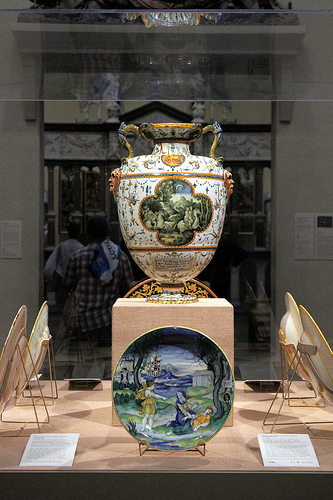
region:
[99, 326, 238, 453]
gold rimmed plate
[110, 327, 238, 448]
gold rimmed plate with a painting drawn in the middle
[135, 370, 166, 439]
painting of an angel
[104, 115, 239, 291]
vase with painting on it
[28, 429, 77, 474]
white piece of paper with text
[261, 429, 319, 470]
white piece of paper with text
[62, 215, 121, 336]
reflection of a person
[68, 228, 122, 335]
reflection of a person in a plaid shirt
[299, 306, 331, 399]
gold rimmed plate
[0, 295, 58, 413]
gold rimmed plates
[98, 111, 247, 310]
two handled ornate vase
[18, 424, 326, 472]
two white placards in front of display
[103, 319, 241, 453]
round ceramic painted plate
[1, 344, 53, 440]
metal display bracket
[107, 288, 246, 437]
foundation block for vase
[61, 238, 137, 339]
reflection of plaid shirt in glass window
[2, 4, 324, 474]
glass window of display case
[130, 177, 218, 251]
clover shaped green painting on front of vase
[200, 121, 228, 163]
gold and blue handle on vase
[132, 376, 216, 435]
person reaching out to fallen person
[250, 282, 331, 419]
China on display.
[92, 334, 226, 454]
A plate on a rack.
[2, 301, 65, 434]
Plates on the rack.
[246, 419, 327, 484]
A paper on the display table.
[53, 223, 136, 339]
People walking thru the door.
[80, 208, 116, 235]
The person is wearing a cap.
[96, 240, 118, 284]
A jersey on the man shoulder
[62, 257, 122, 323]
The shirt is plead.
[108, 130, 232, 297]
A vase on top of the concrete block.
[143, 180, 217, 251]
A clover on front of vase.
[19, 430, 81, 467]
white paper by plate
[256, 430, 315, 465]
white paper by plate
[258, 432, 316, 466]
white paper with writing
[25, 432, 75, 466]
white paper with writing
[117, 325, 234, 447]
plate on display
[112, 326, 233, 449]
plate with artful painting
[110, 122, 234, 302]
vase above the plate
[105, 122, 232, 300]
vase made with intricacy and care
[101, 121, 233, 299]
vase full of decorations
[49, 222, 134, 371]
reflection in the glass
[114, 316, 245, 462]
decorative plate on display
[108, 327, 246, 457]
artwork painted on plate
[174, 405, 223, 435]
man laying by road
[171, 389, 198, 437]
older gentleman helping man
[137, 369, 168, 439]
man walking along road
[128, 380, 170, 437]
man pointing to fallen gentleman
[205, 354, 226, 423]
trees are painted crooked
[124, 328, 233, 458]
bright colors used in painting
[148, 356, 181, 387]
ship on turbulent waters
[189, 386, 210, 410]
green grass near path